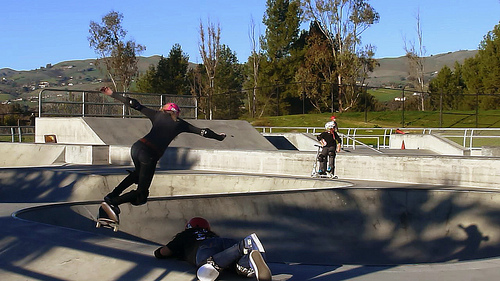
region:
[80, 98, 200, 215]
skateboarder on the ramp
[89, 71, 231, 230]
the skater doing a trick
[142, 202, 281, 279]
the person alying on the ramp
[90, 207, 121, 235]
the board in the air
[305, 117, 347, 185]
the child on a scooter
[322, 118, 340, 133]
the white helmet on the head of the child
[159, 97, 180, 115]
the pink helmet on the head of the skater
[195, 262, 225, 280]
the white knee pad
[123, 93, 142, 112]
the elbow pad on the skaters arm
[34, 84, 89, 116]
the rail at the top of the ramp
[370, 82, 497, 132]
the black chain link fence on the grass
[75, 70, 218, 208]
person skateboarding on the ramp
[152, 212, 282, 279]
person laying down on the ramp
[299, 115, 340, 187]
person on a scooter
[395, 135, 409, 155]
cone by the ramp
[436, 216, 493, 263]
shadows on the ramp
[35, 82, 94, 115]
railing on the ramp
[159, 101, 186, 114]
pink helmet on the head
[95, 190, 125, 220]
black sneaker on the foot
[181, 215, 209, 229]
red helmet on the person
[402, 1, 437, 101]
bare tree behind the fence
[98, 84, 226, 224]
A girl skating in all black with a pink helmet.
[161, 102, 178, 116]
A pink helmet on a girl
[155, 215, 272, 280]
A guy lying down with a red helmet on.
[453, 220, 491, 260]
Shadow of the girl skater on the bowl.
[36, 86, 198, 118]
Silver railing up a ramp to the left.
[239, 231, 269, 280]
Blue and white sneakers on a guy lying down.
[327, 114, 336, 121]
Red helmet on a person.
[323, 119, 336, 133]
White helmet on a skater.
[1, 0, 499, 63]
Blue sky above.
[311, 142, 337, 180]
A small razor scooter.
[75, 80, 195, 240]
the girl is skateboarding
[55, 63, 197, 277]
the girl is skateboarding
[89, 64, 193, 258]
the girl is skateboarding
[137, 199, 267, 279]
the girl on the ramp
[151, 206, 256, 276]
the girl on the ramp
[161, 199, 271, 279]
the girl on the ramp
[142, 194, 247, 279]
the girl on the ramp